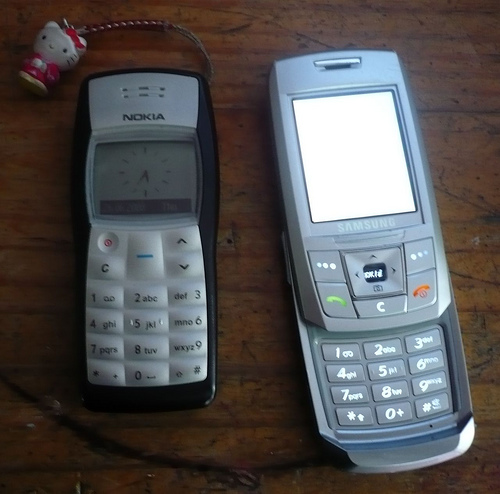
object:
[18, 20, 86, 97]
charm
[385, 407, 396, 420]
"0" button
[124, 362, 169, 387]
"0" button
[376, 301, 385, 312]
letter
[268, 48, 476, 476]
cell phone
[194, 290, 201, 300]
number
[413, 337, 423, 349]
number 3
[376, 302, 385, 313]
letter c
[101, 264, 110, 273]
letter c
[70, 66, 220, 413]
phone